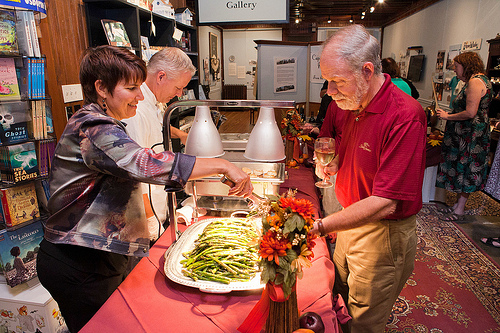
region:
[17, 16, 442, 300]
a group of people at table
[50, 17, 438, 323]
group of people standing at a table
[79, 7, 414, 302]
group of people standing at a buffet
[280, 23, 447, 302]
a man holding a wine glass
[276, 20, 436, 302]
a man drinking wine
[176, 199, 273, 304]
a plate of food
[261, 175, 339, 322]
a vase of flowers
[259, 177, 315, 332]
a vase with orange flowers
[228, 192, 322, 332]
flowers on a table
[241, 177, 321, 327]
a vase of flowers on the table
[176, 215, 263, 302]
A plate of Aspargus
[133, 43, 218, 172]
A chef setting up food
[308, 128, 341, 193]
A glass of white wine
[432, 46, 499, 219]
A woman in a dress having a conversation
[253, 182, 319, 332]
A vase full of Orange flowers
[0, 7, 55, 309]
A rack full of reading books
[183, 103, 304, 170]
Heat Lamps to keep the food warm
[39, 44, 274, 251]
Woman serving aspargus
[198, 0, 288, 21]
A sign with the word "Gallery" on it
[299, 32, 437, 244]
Man in red shirt waiting to be served aspargus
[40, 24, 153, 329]
woman wearing print jacket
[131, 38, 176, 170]
man wearing a white shirt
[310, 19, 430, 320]
man wearing a red shirt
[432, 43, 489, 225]
woman wearing a black dress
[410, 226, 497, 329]
oriental carpet on floor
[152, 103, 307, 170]
two silver heat lamps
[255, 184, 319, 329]
vase of orange flowers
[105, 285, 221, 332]
red table cloth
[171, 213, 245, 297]
green asparagus on a tray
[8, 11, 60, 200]
books on a shelf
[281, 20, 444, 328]
older man wearing red shirt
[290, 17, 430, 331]
man wearing red collared shirt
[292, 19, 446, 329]
man with short and thinning hair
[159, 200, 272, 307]
sliver platter with asparagus on top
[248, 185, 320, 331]
bouquet of artificial flowers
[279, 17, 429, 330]
man with grey hair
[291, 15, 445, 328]
man wearing khaki pants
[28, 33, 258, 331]
woman serving asparagus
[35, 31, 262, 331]
woman holding tongs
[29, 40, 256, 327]
woman with short dark hair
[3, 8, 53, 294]
books on a book rack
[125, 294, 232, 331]
tablecloth is red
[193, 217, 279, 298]
asparagus on a platter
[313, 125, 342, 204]
man holding a wine glass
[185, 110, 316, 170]
heat lamps for food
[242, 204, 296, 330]
flowers in a vase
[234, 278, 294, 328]
red bow around the vase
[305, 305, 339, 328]
apple on the table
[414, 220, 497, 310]
rug on the floor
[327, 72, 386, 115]
man has a beard